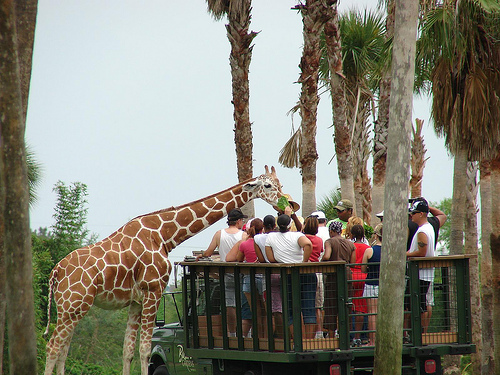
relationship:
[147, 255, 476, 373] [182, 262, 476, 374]
truck has back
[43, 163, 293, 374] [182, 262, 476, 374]
giraffe over back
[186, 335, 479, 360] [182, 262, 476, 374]
platform on back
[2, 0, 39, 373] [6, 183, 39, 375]
tree has trunk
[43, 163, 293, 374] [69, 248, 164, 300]
giraffe has spots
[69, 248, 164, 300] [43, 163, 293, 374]
spots are on giraffe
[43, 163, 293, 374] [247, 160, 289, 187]
giraffe has top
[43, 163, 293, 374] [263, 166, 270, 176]
giraffe has ossicone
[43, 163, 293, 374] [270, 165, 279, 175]
giraffe has ossicone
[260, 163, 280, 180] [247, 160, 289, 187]
ossicones are on top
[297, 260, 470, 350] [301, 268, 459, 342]
fence has grid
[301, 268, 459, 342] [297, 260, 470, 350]
grid made of fence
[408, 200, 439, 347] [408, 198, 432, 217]
man has cap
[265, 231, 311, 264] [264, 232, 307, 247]
shirt has sleeves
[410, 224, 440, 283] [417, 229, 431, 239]
shirt has sleeves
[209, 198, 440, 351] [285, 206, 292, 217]
people have hand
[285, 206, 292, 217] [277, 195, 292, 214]
hand are holding food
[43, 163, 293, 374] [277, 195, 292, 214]
giraffe eating food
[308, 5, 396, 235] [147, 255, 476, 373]
tree behind car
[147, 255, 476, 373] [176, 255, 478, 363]
truck has wagon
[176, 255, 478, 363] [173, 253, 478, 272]
wagon has railing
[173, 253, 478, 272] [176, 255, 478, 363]
railing surrounds wagon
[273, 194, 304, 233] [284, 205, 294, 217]
person has hand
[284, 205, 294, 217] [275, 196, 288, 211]
hand holding leaf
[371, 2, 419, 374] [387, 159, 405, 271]
tree has bark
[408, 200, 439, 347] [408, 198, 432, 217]
man wearing hat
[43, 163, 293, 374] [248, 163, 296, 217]
giraffe has head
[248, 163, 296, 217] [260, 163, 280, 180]
head has horns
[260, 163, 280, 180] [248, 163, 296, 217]
horns are on head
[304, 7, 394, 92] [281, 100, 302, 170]
palm has leaf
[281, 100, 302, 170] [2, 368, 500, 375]
leaf hanging down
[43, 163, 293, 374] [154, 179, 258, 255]
giraffe has neck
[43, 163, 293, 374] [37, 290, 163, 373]
giraffe has legs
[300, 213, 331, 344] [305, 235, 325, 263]
person wearing shirt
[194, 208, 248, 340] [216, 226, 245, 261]
people wearing shirt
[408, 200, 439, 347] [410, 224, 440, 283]
man wearing shirt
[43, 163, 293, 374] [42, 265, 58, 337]
giraffe has tail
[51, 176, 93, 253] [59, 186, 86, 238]
tree has leaves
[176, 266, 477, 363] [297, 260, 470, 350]
deck has fence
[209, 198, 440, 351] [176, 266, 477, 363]
people are on deck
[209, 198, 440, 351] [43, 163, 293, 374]
people are observing giraffe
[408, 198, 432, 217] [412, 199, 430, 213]
cap has color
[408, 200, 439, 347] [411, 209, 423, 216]
man has sunglasses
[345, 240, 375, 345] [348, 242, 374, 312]
woman has outfit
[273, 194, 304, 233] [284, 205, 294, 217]
man has hand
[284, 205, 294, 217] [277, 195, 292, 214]
hand has food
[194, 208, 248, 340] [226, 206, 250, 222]
people wearing cap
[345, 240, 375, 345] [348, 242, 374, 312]
woman wearing dress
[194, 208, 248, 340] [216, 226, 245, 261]
people dressed in shirt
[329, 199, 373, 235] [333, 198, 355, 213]
man wearing cap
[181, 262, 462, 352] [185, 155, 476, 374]
cage for safety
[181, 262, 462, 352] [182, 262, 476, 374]
cage on back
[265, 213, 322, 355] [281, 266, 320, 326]
woman dressed in capris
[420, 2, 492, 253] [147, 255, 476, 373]
tree next to truck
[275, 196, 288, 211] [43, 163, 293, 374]
leaf for giraffe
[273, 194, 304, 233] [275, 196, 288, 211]
man holding leaf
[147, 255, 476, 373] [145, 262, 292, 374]
truck has side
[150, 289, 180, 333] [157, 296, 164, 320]
mirror has view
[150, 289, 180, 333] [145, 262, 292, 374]
mirror on side